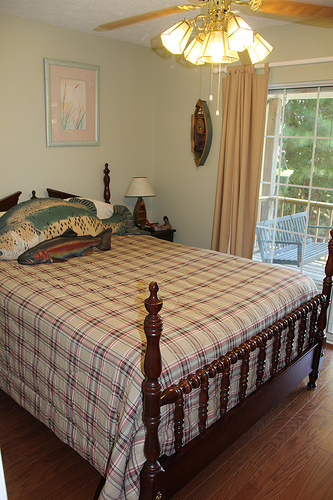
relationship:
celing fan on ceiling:
[96, 1, 332, 101] [10, 1, 332, 61]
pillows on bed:
[0, 196, 137, 263] [2, 166, 332, 490]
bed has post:
[2, 166, 332, 490] [79, 168, 332, 315]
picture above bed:
[45, 65, 98, 147] [2, 166, 332, 490]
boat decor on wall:
[187, 100, 216, 169] [2, 22, 226, 249]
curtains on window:
[206, 60, 260, 260] [221, 80, 330, 264]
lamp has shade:
[122, 176, 160, 225] [123, 179, 163, 200]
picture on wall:
[45, 65, 98, 147] [2, 22, 226, 249]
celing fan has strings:
[96, 1, 332, 101] [211, 62, 230, 121]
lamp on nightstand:
[122, 176, 160, 225] [128, 219, 186, 241]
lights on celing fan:
[161, 8, 270, 76] [96, 1, 332, 101]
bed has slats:
[2, 166, 332, 490] [144, 292, 332, 481]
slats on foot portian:
[144, 292, 332, 481] [123, 223, 330, 488]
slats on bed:
[144, 292, 332, 481] [2, 166, 332, 490]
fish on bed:
[16, 220, 113, 270] [2, 166, 332, 490]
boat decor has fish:
[187, 100, 216, 169] [197, 109, 202, 142]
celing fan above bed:
[96, 1, 332, 101] [2, 166, 332, 490]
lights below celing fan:
[161, 8, 270, 76] [96, 1, 332, 101]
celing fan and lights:
[96, 1, 332, 101] [161, 8, 270, 76]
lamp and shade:
[122, 176, 160, 225] [123, 179, 163, 200]